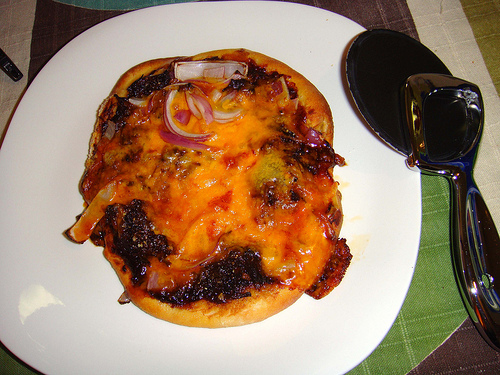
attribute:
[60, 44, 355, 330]
pizza — baked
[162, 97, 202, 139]
onion — red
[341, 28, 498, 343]
spoon — metal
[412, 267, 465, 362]
placemat — green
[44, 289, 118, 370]
plate — white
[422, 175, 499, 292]
pattern — green, white, plaid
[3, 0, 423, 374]
plate — white, round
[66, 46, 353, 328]
pizza cutter — silver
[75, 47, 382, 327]
food — red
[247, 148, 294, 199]
spot — green